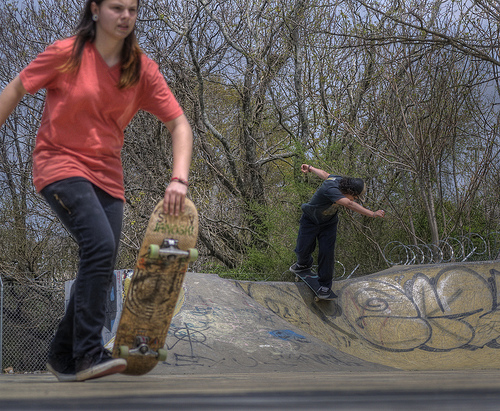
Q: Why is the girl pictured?
A: Skating.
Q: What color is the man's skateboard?
A: Black.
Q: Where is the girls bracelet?
A: Wrist.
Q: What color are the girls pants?
A: Black.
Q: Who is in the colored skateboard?
A: Brown.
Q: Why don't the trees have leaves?
A: It is fall season.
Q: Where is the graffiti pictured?
A: Skate rink.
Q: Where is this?
A: Skatepark.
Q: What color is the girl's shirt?
A: Peach.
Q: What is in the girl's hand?
A: Skateboard.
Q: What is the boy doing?
A: Balancing.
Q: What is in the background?
A: Trees.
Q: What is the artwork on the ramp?
A: Graffiti.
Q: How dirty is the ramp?
A: Very dirty.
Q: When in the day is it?
A: Afternoon.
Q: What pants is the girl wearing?
A: Jeans.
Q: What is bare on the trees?
A: Tree limbs.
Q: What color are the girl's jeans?
A: Blue.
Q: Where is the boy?
A: Background.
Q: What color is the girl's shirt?
A: Mango.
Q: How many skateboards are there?
A: Two.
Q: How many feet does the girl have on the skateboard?
A: None.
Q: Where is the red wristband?
A: Girl's left wrist.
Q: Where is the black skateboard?
A: Under the boy in back.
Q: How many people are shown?
A: Two.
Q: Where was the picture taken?
A: Skatepark.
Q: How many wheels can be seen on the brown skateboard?
A: Four.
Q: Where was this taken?
A: Skate park.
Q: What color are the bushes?
A: Green.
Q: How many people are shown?
A: 2.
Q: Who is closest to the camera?
A: The girl.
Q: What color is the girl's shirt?
A: Red.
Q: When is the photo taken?
A: Daylight.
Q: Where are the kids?
A: Skatepark.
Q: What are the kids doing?
A: Skateboarding.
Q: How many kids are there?
A: Two.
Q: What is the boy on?
A: Ramp.